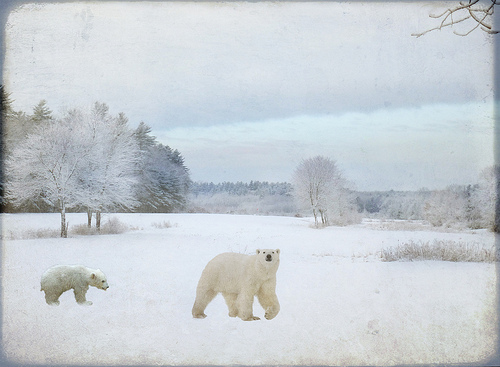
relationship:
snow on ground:
[154, 219, 186, 235] [130, 222, 200, 279]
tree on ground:
[27, 109, 143, 230] [130, 222, 200, 279]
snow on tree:
[154, 219, 186, 235] [27, 109, 143, 230]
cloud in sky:
[226, 43, 282, 87] [197, 54, 319, 127]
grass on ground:
[389, 229, 460, 263] [130, 222, 200, 279]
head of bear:
[244, 238, 283, 279] [189, 220, 326, 333]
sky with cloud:
[197, 54, 319, 127] [226, 43, 282, 87]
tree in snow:
[27, 109, 143, 230] [154, 219, 186, 235]